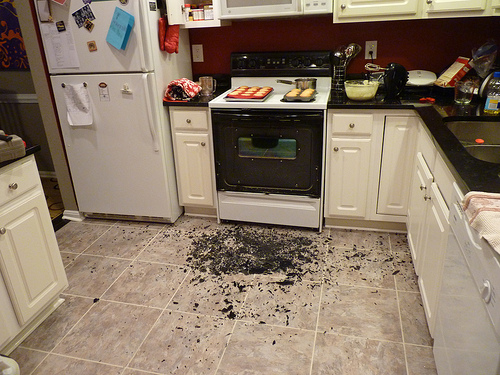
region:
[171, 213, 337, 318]
Black stuff on ground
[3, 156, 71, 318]
white cabinets with handle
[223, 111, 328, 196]
Black oven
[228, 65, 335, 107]
food and pot above oven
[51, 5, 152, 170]
Fridge with many things on it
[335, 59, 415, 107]
mixture in a bowl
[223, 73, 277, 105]
Food item in rows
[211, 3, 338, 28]
white microwave above oven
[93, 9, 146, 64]
Blue paper hanging on fridge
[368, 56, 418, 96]
Black mixer next to mixture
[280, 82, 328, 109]
Metal pan filled with food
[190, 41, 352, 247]
Black and white oven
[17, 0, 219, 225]
White metal fridge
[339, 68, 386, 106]
Clear glass bowl with food inside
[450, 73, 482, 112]
Clear glass measuring cup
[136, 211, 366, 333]
Broken glass on the floor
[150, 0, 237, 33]
Kitchen cabinet with open door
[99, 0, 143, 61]
Blue paper hanging from fridge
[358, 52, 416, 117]
Black plastic mixing tool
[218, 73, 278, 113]
Red plastic pan with food inside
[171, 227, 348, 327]
a bunch of dirt on the ground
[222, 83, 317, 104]
some muffins on top of the stove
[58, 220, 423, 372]
the tile floor in the kitchen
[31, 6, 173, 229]
the white fridge in the kitchen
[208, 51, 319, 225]
the oven and stove in the kitchen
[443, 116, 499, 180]
the sink on the side of the kitchen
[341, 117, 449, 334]
a row of cabinets in the kitchen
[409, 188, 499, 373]
the dishwasher in the room.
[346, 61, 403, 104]
the mixing bowl by the kitchen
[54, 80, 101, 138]
the paper on the fridge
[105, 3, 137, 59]
a blue card on the fridge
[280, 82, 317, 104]
six cupcakes cooling off on top the stove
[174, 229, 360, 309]
broken glass on the floor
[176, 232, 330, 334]
pieces of black glass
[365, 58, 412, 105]
a black handmixer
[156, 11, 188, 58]
two red oven mitts hanging on the fridge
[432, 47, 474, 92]
an empty cake mix box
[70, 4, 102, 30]
a photograph postcard on the fridge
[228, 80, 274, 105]
12 cupcakes in a red pan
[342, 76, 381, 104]
glass bowl of cake batter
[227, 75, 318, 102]
Food over on the trays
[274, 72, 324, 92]
Pot over the stove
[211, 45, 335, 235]
Black and white oven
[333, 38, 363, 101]
Kitchen wares on the counter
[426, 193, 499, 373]
White dish washer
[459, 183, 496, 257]
Towel over the dish washer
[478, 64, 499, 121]
Oil on the counter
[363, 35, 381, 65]
White plug in on the wall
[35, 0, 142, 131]
Papers on the refrigerator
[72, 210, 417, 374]
Black dirt on the floor